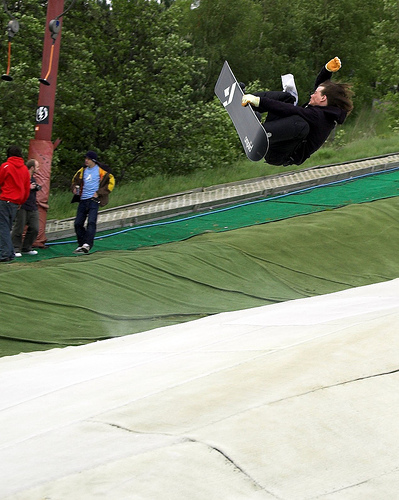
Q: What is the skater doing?
A: A trick.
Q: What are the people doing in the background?
A: Talking.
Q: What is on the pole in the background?
A: A sign.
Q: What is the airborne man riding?
A: A skateboard.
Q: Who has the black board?
A: The man.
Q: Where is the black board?
A: By the man's feet.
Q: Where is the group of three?
A: Near the pole.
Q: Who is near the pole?
A: The group of three men.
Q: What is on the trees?
A: Leaves.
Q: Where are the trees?
A: Behind the group of three.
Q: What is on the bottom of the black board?
A: White writing.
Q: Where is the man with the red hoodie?
A: On the left.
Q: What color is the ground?
A: Green.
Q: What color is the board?
A: Black.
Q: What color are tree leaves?
A: Green.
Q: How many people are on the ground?
A: 3.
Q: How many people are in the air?
A: 1.